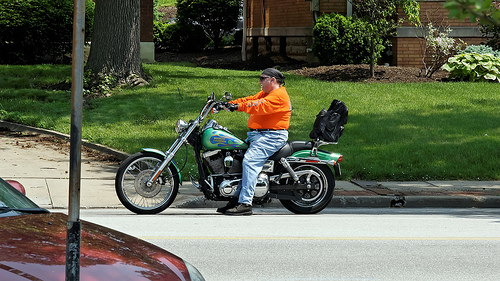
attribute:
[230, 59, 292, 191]
man — sitting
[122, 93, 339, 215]
motorcycle — green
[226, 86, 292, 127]
jacket — orange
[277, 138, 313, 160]
seat — leather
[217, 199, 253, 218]
shoes — black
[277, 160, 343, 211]
tire — black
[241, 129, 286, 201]
pants — jeans, denim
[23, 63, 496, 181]
grass — green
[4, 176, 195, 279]
car — parked, red, sitting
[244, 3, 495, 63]
building — brick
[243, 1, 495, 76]
exterior — brick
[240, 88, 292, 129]
shirt — orange, long sleeved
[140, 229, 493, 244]
line — yellow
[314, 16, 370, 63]
bush — green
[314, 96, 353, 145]
bag — black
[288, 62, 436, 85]
dirt — brown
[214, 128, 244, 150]
flames — blue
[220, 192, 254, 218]
boots — black